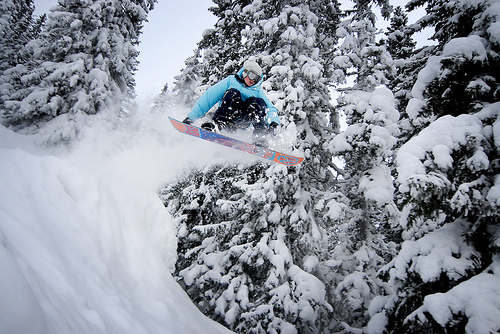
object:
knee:
[246, 97, 264, 108]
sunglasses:
[246, 71, 258, 81]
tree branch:
[318, 156, 352, 183]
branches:
[188, 175, 279, 236]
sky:
[143, 0, 198, 78]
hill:
[1, 123, 236, 333]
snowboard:
[167, 114, 304, 168]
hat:
[241, 57, 265, 72]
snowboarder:
[181, 59, 281, 147]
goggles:
[246, 71, 264, 79]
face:
[242, 71, 261, 88]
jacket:
[187, 79, 279, 123]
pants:
[214, 88, 272, 130]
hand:
[181, 117, 196, 126]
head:
[240, 60, 264, 87]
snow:
[453, 279, 500, 315]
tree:
[383, 1, 498, 333]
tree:
[372, 4, 428, 126]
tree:
[0, 0, 139, 114]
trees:
[195, 1, 342, 56]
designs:
[166, 115, 303, 167]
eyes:
[249, 75, 255, 79]